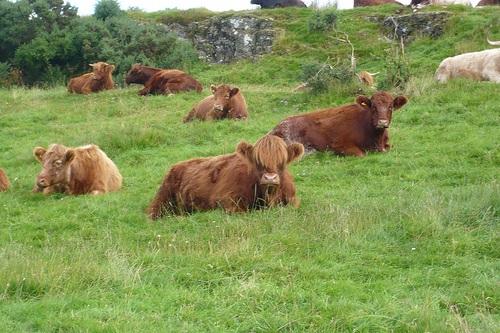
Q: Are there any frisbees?
A: No, there are no frisbees.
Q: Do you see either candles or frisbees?
A: No, there are no frisbees or candles.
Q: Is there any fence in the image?
A: No, there are no fences.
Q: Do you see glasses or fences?
A: No, there are no fences or glasses.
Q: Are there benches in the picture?
A: No, there are no benches.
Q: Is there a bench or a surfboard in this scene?
A: No, there are no benches or surfboards.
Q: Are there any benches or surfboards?
A: No, there are no benches or surfboards.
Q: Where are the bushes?
A: The bushes are on the grass.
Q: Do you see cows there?
A: Yes, there is a cow.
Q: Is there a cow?
A: Yes, there is a cow.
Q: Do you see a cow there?
A: Yes, there is a cow.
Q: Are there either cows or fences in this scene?
A: Yes, there is a cow.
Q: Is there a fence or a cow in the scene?
A: Yes, there is a cow.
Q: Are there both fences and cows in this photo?
A: No, there is a cow but no fences.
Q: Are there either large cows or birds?
A: Yes, there is a large cow.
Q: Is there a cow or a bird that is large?
A: Yes, the cow is large.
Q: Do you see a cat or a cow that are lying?
A: Yes, the cow is lying.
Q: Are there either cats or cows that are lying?
A: Yes, the cow is lying.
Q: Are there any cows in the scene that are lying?
A: Yes, there is a cow that is lying.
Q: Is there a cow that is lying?
A: Yes, there is a cow that is lying.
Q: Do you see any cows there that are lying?
A: Yes, there is a cow that is lying.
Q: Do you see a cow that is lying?
A: Yes, there is a cow that is lying.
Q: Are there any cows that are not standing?
A: Yes, there is a cow that is lying.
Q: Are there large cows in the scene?
A: Yes, there is a large cow.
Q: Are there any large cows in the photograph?
A: Yes, there is a large cow.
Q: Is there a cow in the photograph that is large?
A: Yes, there is a cow that is large.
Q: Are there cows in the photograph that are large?
A: Yes, there is a cow that is large.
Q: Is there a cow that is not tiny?
A: Yes, there is a large cow.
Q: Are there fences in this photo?
A: No, there are no fences.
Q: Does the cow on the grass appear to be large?
A: Yes, the cow is large.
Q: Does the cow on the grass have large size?
A: Yes, the cow is large.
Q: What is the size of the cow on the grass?
A: The cow is large.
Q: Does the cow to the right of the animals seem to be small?
A: No, the cow is large.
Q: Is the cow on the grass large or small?
A: The cow is large.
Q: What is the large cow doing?
A: The cow is lying.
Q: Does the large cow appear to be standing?
A: No, the cow is lying.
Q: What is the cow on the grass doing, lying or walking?
A: The cow is lying.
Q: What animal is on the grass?
A: The animal is a cow.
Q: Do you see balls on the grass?
A: No, there is a cow on the grass.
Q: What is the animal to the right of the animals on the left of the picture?
A: The animal is a cow.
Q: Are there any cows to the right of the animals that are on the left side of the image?
A: Yes, there is a cow to the right of the animals.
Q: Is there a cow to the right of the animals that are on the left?
A: Yes, there is a cow to the right of the animals.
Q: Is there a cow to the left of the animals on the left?
A: No, the cow is to the right of the animals.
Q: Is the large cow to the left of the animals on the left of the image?
A: No, the cow is to the right of the animals.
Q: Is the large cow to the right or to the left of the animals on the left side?
A: The cow is to the right of the animals.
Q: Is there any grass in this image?
A: Yes, there is grass.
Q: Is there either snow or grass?
A: Yes, there is grass.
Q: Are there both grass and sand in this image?
A: No, there is grass but no sand.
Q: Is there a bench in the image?
A: No, there are no benches.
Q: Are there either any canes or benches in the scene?
A: No, there are no benches or canes.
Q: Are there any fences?
A: No, there are no fences.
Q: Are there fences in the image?
A: No, there are no fences.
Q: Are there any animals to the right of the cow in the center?
A: No, the animals are to the left of the cow.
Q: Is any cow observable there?
A: Yes, there is a cow.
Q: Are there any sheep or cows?
A: Yes, there is a cow.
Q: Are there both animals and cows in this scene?
A: Yes, there are both a cow and animals.